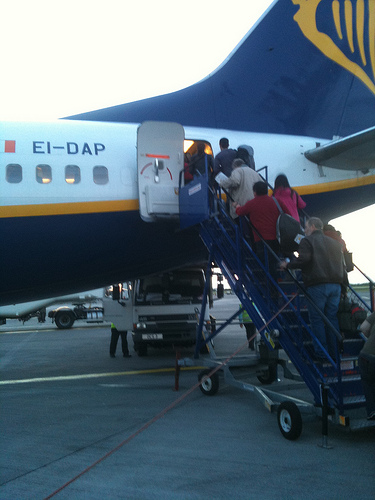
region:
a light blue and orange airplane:
[1, 0, 365, 311]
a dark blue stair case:
[180, 156, 368, 425]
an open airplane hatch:
[129, 112, 192, 227]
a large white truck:
[105, 266, 220, 356]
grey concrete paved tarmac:
[3, 314, 372, 495]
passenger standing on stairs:
[285, 213, 342, 354]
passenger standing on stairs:
[236, 177, 287, 280]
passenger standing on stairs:
[219, 153, 261, 222]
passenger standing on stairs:
[268, 171, 302, 231]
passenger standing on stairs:
[208, 131, 236, 176]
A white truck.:
[101, 255, 218, 364]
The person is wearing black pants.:
[100, 323, 130, 359]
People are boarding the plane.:
[180, 135, 372, 397]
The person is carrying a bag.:
[231, 174, 294, 259]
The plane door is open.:
[130, 116, 223, 227]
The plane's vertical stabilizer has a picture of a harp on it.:
[220, 0, 370, 171]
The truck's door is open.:
[92, 270, 215, 347]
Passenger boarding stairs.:
[172, 145, 370, 426]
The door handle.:
[138, 153, 168, 183]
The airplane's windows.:
[0, 145, 123, 221]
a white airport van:
[107, 247, 237, 373]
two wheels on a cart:
[181, 344, 305, 450]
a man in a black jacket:
[273, 217, 363, 288]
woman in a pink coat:
[267, 171, 316, 234]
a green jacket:
[221, 286, 261, 329]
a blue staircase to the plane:
[180, 180, 371, 425]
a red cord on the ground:
[43, 378, 183, 496]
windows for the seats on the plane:
[0, 152, 116, 208]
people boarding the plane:
[173, 126, 365, 346]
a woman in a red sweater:
[237, 183, 293, 243]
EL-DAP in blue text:
[18, 136, 119, 166]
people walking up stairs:
[211, 144, 373, 323]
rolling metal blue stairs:
[178, 189, 372, 450]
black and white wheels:
[191, 363, 312, 442]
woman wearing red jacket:
[237, 180, 290, 265]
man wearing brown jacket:
[291, 215, 361, 290]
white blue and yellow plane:
[2, 114, 165, 292]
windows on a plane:
[8, 159, 117, 187]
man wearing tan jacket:
[221, 156, 267, 219]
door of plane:
[129, 115, 201, 226]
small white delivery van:
[85, 246, 238, 376]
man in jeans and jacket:
[265, 206, 356, 367]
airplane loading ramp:
[150, 125, 373, 461]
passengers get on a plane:
[3, 4, 373, 373]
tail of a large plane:
[4, 4, 374, 291]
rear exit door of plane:
[124, 104, 200, 234]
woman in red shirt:
[225, 174, 296, 307]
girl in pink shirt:
[262, 165, 315, 237]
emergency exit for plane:
[114, 99, 259, 239]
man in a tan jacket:
[205, 148, 274, 240]